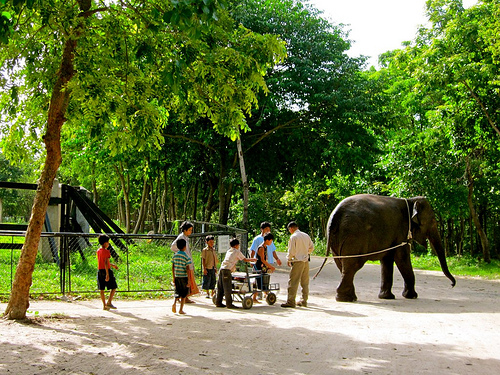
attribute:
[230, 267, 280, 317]
wagon — metal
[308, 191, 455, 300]
elephant — walking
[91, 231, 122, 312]
boy — lagging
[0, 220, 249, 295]
fence — chain link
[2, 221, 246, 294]
area — grassy, park-like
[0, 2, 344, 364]
tree — tall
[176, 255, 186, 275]
shirt — green, white, striped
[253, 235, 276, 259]
shirt — blue